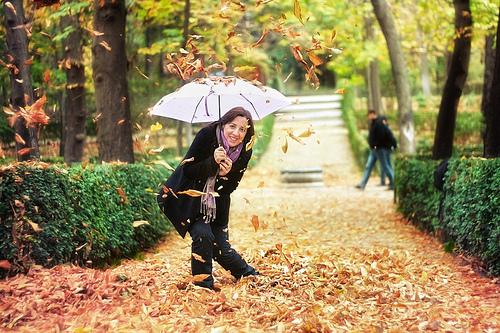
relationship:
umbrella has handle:
[147, 58, 299, 142] [215, 93, 228, 166]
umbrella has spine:
[147, 76, 294, 147] [192, 97, 212, 112]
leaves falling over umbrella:
[2, 0, 500, 332] [153, 70, 292, 122]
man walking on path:
[352, 106, 397, 188] [0, 95, 499, 333]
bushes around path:
[390, 152, 497, 249] [6, 86, 496, 331]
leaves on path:
[2, 0, 500, 332] [6, 86, 496, 331]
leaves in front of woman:
[2, 0, 500, 332] [166, 105, 266, 293]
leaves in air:
[2, 2, 358, 283] [281, 125, 353, 193]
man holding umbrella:
[156, 106, 259, 291] [146, 75, 293, 121]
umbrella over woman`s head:
[147, 76, 294, 147] [216, 102, 253, 148]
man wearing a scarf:
[156, 106, 259, 291] [208, 121, 240, 220]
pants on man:
[172, 197, 264, 292] [156, 106, 259, 291]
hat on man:
[365, 107, 375, 114] [352, 106, 397, 188]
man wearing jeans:
[148, 74, 410, 226] [354, 145, 398, 187]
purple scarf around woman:
[197, 125, 243, 224] [153, 102, 289, 293]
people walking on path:
[362, 104, 398, 189] [261, 73, 400, 316]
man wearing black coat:
[156, 106, 259, 291] [158, 122, 255, 238]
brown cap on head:
[365, 107, 380, 116] [367, 107, 378, 117]